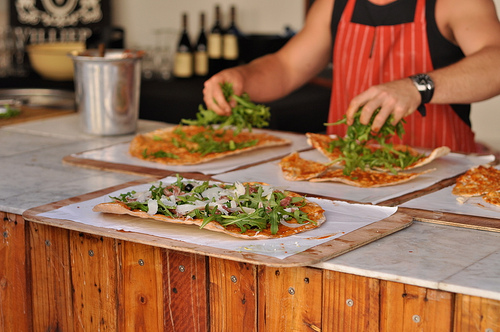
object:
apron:
[327, 1, 474, 153]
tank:
[326, 1, 472, 129]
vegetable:
[221, 195, 309, 234]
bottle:
[171, 10, 195, 80]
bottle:
[192, 13, 212, 79]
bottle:
[206, 3, 223, 64]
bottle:
[220, 4, 238, 62]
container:
[67, 38, 142, 137]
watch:
[407, 72, 435, 117]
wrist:
[405, 64, 442, 111]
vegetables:
[225, 91, 260, 109]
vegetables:
[320, 114, 348, 129]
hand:
[343, 72, 420, 137]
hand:
[200, 68, 248, 117]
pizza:
[65, 122, 311, 176]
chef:
[199, 0, 497, 153]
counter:
[0, 112, 499, 330]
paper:
[34, 175, 396, 261]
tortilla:
[278, 128, 455, 194]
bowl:
[22, 41, 94, 79]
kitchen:
[0, 1, 499, 331]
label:
[173, 52, 193, 78]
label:
[194, 52, 209, 74]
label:
[205, 31, 220, 60]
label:
[223, 35, 236, 60]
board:
[19, 176, 416, 269]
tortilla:
[90, 170, 325, 240]